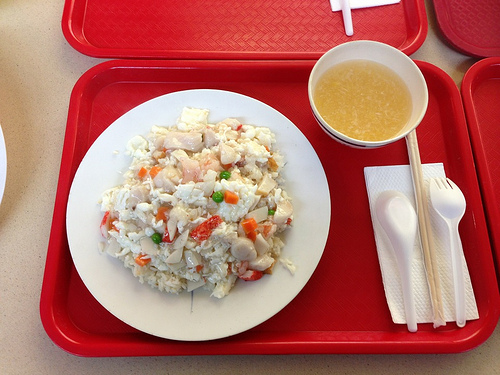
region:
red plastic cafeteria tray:
[57, 53, 497, 356]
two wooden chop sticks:
[406, 124, 448, 331]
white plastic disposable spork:
[429, 174, 474, 328]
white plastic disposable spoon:
[374, 187, 422, 330]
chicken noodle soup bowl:
[308, 38, 425, 150]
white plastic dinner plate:
[64, 88, 332, 340]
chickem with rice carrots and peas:
[97, 105, 301, 304]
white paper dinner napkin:
[361, 161, 481, 326]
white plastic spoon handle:
[333, 5, 360, 37]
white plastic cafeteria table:
[3, 1, 498, 373]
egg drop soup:
[313, 56, 408, 149]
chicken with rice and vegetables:
[100, 105, 301, 298]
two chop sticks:
[405, 133, 444, 330]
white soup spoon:
[375, 179, 427, 337]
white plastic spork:
[427, 171, 488, 335]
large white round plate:
[51, 63, 365, 342]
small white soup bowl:
[303, 22, 433, 164]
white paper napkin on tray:
[355, 151, 498, 328]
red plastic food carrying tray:
[45, 35, 495, 361]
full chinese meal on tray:
[59, 56, 467, 318]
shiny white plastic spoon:
[375, 187, 432, 309]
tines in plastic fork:
[418, 161, 468, 201]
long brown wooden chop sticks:
[402, 127, 462, 332]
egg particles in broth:
[345, 87, 394, 119]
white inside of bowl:
[340, 55, 409, 89]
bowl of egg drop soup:
[297, 30, 441, 134]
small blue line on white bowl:
[307, 115, 373, 152]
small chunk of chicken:
[228, 234, 274, 269]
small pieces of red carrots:
[225, 212, 274, 246]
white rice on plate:
[125, 251, 202, 293]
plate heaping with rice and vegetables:
[69, 88, 331, 333]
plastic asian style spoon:
[373, 184, 431, 336]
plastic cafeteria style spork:
[431, 170, 487, 327]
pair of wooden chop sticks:
[403, 130, 450, 337]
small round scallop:
[230, 231, 257, 263]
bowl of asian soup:
[310, 37, 434, 145]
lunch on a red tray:
[37, 53, 494, 360]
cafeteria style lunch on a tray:
[53, 53, 490, 360]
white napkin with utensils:
[365, 151, 495, 335]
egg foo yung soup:
[305, 35, 436, 143]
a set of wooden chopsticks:
[396, 145, 434, 340]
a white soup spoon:
[352, 160, 417, 345]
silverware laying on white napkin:
[365, 158, 479, 343]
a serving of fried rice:
[88, 106, 295, 315]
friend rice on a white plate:
[55, 74, 326, 351]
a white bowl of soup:
[302, 36, 426, 149]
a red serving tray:
[90, 1, 310, 50]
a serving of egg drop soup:
[325, 63, 407, 137]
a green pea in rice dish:
[210, 188, 227, 207]